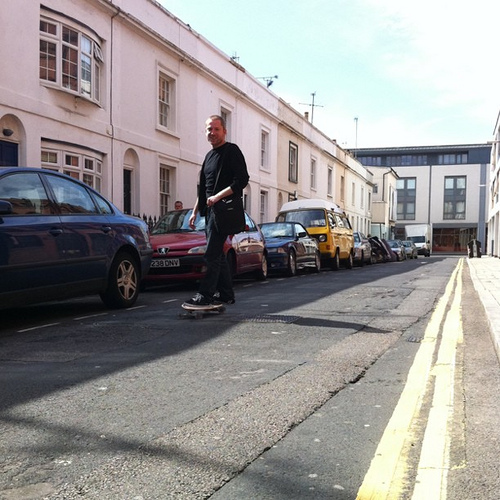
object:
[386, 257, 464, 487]
line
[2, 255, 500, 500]
road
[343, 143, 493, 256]
building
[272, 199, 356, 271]
bus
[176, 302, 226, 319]
stakeboard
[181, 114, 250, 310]
man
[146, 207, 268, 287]
car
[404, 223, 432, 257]
truck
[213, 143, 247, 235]
bag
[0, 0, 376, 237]
building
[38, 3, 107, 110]
window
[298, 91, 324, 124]
antenna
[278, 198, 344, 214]
roof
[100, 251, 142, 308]
tire